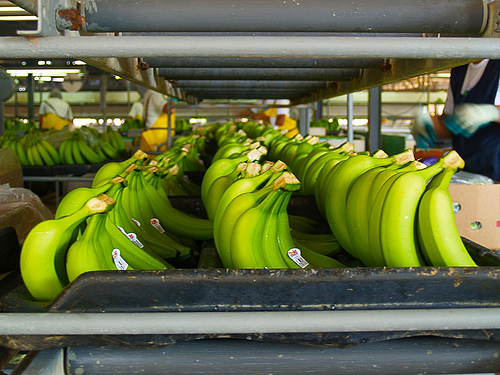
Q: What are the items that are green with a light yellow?
A: Bananas.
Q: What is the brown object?
A: Box.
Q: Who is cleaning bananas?
A: A person with gloves.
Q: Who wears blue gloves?
A: A woman.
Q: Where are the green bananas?
A: On a counter.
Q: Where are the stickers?
A: On bananas.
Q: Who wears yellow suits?
A: Laborers.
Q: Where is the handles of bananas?
A: In a factory.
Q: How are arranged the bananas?
A: In a line.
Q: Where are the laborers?
A: In a storehouse.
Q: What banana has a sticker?
A: The green one.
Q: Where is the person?
A: Beside the shelf.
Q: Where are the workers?
A: Back ground.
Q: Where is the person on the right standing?
A: In front of a box.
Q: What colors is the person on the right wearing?
A: White and navy.